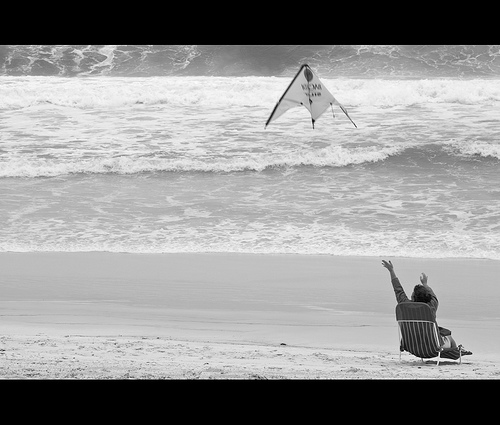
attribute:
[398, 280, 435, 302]
person — sitting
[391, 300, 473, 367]
chair — portable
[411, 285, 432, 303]
head — ambiguous, unidentified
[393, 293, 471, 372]
chair — striped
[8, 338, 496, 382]
area — Rocky, sandy, grassy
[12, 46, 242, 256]
water — rough, choppy, salty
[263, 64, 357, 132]
kite — white, triangular